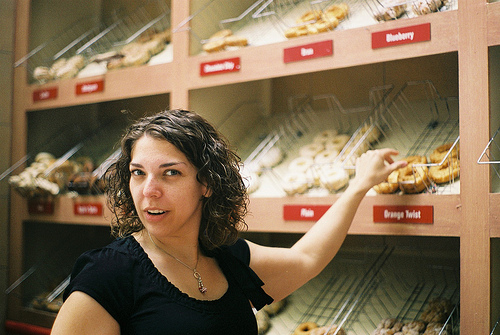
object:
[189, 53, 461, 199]
shelves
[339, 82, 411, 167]
wire bin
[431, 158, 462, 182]
bagels